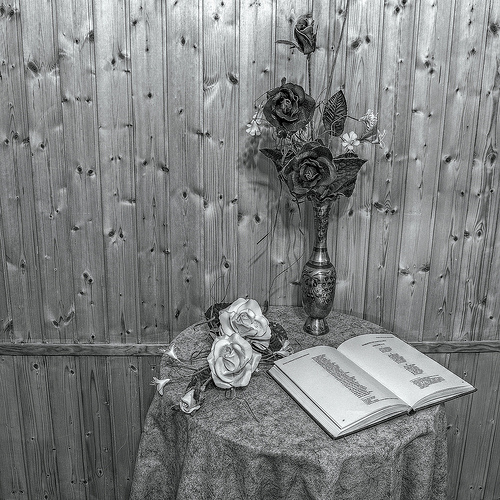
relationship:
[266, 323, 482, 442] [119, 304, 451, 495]
book on table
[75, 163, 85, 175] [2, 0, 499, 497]
holes in wall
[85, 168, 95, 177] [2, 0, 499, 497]
holes in wall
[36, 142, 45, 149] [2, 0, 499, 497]
holes in wall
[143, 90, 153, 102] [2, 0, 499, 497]
holes in wall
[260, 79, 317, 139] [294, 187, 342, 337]
flower in vase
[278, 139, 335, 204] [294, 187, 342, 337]
flower in vase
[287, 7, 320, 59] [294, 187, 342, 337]
flower in vase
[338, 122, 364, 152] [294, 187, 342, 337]
flower in vase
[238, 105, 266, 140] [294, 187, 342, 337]
flower in vase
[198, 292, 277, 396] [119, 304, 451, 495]
flowers on table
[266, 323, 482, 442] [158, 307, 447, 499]
book on table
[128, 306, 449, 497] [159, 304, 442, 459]
table cloth on table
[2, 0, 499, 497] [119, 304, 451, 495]
wall behind table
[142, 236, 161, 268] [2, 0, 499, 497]
knot in wall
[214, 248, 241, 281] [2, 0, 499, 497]
knot in wall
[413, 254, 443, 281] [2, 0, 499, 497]
knot in wall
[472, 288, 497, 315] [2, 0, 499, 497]
knot in wall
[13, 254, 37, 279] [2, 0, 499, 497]
knot in wall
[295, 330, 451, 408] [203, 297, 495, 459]
words on pages.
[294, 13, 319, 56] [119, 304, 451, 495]
flower on table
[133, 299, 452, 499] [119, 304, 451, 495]
table cloth on table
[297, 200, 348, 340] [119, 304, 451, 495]
vase on table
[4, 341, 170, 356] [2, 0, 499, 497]
line on wall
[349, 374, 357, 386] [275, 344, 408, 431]
words on page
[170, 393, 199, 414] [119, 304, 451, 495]
petal on table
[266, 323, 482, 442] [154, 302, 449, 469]
book on table top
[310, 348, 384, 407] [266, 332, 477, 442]
words on book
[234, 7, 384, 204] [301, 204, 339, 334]
bouquet in vase